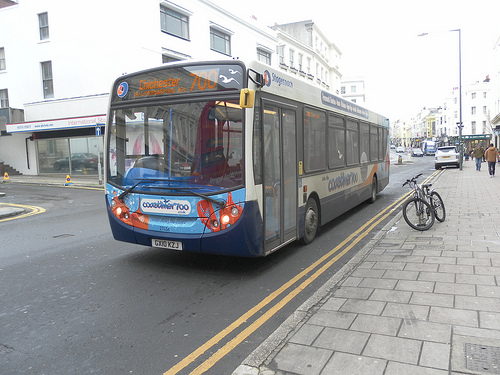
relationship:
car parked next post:
[431, 142, 464, 171] [416, 23, 471, 137]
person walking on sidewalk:
[483, 140, 498, 176] [388, 157, 500, 368]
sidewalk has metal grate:
[388, 157, 500, 368] [410, 172, 435, 225]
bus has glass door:
[92, 50, 399, 274] [257, 91, 310, 248]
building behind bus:
[5, 2, 373, 132] [92, 50, 399, 274]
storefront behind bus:
[434, 131, 490, 161] [92, 50, 399, 274]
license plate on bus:
[148, 233, 185, 254] [92, 50, 399, 274]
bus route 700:
[92, 50, 399, 274] [184, 65, 223, 96]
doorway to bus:
[257, 91, 310, 248] [92, 50, 399, 274]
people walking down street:
[459, 138, 499, 176] [388, 157, 500, 368]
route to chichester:
[103, 57, 252, 103] [129, 73, 190, 94]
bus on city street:
[92, 50, 399, 274] [8, 210, 371, 359]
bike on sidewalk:
[397, 169, 448, 233] [388, 157, 500, 368]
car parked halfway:
[431, 142, 464, 171] [384, 125, 500, 232]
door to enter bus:
[257, 91, 310, 248] [92, 50, 399, 274]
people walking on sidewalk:
[459, 138, 499, 176] [388, 157, 500, 368]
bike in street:
[397, 169, 448, 233] [388, 157, 500, 368]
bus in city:
[92, 50, 399, 274] [6, 1, 500, 375]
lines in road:
[152, 240, 352, 374] [8, 210, 371, 359]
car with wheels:
[431, 142, 464, 171] [455, 160, 464, 168]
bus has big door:
[92, 50, 399, 274] [257, 91, 310, 248]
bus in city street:
[92, 50, 399, 274] [8, 210, 371, 359]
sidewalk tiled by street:
[388, 157, 500, 368] [8, 210, 371, 359]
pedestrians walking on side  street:
[459, 138, 499, 176] [388, 157, 500, 368]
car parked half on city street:
[431, 142, 464, 171] [388, 157, 500, 368]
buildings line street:
[383, 80, 494, 153] [388, 157, 500, 368]